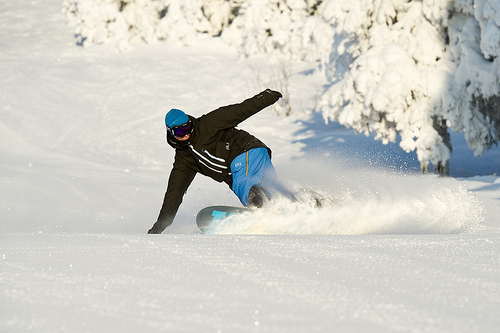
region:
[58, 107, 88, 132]
this is a patch of snow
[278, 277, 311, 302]
this is a patch of snow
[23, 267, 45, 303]
this is a patch of snow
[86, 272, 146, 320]
this is a patch of snow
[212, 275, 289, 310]
this is a patch of snow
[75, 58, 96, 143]
this is a patch of snow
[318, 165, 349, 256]
this is a patch of snow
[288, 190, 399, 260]
this is a patch of snow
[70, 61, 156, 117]
this is a patch of snow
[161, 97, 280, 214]
that is aperson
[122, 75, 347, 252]
snowboarder in the snow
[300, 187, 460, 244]
snow spraying from snowboard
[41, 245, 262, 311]
white snow on the ground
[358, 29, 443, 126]
white snow on the trees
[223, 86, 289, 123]
left arm of snowboarder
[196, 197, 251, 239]
front of a snowboard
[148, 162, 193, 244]
right arm of a snowboarder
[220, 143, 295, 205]
blue snow pants on a man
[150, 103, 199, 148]
head of a snowboarder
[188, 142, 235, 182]
stripes on a jacket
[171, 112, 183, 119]
man wearing blue cap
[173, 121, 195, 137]
man wearing purple goggles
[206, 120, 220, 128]
man wearing black jacket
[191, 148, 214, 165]
white stripes on jacket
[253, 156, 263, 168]
man wearing blue pants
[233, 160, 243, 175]
white symbol on pants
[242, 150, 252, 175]
yellow stripe on pants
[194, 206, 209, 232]
tip of ski board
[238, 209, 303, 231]
snow under ski board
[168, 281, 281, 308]
white snow on ground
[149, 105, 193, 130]
He is weaing a blue hat.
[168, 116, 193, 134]
He has black goggles.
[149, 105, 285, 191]
He has a black jacket.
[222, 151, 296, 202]
He is wearing blue pants.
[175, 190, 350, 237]
His board is black.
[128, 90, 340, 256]
He is boarding.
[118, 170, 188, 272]
He is touching the snow.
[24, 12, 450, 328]
The ground is snow covered.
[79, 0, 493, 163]
The tree is snow covered.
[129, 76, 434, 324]
He is snow boarding down the mountain.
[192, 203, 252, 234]
front end of snow board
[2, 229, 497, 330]
row of snow on ground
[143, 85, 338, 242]
man snowboarding on pass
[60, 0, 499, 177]
snow-covered trees on hill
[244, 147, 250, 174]
orange stripe down side of pants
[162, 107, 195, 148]
hood from winter coat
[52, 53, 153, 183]
snowboard tracks on snow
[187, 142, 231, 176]
pocket and coat zippers on coat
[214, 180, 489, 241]
snow scattering in air from snowboard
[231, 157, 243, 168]
company logo on pants